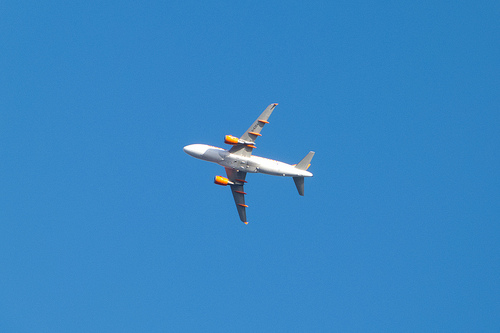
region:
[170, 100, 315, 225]
an airplane flying in the air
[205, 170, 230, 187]
an engine on the plane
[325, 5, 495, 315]
a big chunk of blue sky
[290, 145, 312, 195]
the tail of the plane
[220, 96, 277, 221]
the wings of the plane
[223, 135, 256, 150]
the other engine of the plane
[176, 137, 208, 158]
the front end of the plane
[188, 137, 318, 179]
the body of the plane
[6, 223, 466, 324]
more of the blue sky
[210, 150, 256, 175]
the bottom of the plane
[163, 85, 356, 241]
Airplane flying in sky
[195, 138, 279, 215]
Shadow cast by left wing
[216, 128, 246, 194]
Two orange jets on airplane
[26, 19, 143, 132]
Cloudless blue sky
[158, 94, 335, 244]
Commercial aircraft flying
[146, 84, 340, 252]
Bottom view of airplane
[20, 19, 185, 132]
Bright and sunny day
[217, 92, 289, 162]
Airplane wing with orange accents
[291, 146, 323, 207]
Tail end of aircraft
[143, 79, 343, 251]
White and orange airplane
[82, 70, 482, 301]
a plane in the air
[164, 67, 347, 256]
a plane in the sky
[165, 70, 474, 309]
an airplane in the air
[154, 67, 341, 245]
an airplane in the sky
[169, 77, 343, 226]
a white plane in the air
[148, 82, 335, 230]
a white plane in the sky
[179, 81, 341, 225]
a white airplane in the sky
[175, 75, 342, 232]
a white airplane in the air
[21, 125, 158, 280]
a clear blue sky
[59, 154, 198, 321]
a sky is blue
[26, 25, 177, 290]
The sky is clear, blue, and bright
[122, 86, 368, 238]
The plane is flying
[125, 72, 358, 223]
The plane appears to be on its side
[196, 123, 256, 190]
The plane has two orange engines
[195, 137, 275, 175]
There is a shadow on the bottom of the plane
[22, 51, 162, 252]
There are no clouds in the sky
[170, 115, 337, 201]
The plane's body is white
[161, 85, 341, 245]
The plane is flying to its destination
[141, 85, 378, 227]
The plane is the main focus of this image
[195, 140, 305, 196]
The plane's wheels are not out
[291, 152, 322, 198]
The side wings of the tail of the plane.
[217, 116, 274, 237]
The side wings on the sides of the plane.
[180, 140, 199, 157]
The tip of the plane in the front.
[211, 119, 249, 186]
The orange colored engines on the wings of the plane.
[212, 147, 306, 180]
The bottom area of the plane.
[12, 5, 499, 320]
The bright blue sky.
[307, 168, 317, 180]
The tip of the back of the plane.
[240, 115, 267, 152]
The three orange elements on the left wing.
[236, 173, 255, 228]
The three elements on the right wing of the plane.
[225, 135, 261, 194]
The gray mounts the engines are attached to.